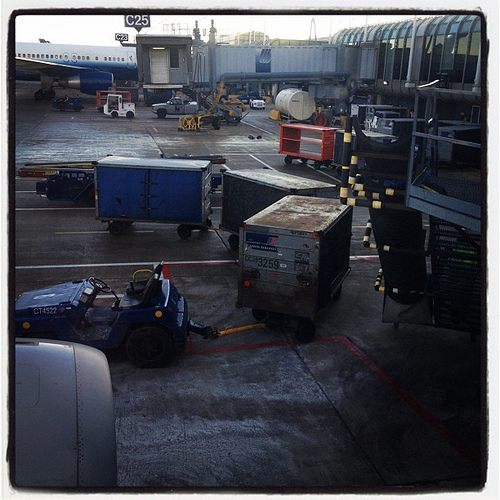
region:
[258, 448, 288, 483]
the ground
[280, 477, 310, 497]
the ground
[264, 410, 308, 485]
the ground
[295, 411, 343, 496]
the ground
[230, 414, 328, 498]
the ground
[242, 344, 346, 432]
the ground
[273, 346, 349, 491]
the ground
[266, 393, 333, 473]
the ground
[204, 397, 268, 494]
the ground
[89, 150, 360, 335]
three carts on tarmac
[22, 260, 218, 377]
blue vehicle on tarmac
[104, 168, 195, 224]
blue side of luggage cart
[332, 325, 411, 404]
red line on tarmac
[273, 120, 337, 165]
empty orange cart on wheels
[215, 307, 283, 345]
yellow rod on cart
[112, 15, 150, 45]
white and blue signs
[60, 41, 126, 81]
body of parked airplane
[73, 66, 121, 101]
blue jet engine under wing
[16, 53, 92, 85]
wing on side of plane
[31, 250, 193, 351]
vehicle on a tarmack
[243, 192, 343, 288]
container on a trarmack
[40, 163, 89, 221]
truck on the tarmack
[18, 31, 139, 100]
airplane at the gate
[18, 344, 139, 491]
engine of an airplane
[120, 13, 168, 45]
sign at an airport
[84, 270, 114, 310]
steering wheel of vehicle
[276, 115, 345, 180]
red cart on the tarmack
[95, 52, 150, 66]
windows on airplane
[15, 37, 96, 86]
wing on an airplane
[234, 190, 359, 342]
luggage cart on the tarmac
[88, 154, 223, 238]
luggage cart on the tarmac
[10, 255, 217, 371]
truck to pull luggage carts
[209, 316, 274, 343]
yellow tow bar on the cart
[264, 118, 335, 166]
an orange luggage cart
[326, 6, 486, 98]
airport terminal with glass windows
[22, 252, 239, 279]
white line on the tarmac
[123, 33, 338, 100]
the jetway on the tarmac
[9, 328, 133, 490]
part of a jet engine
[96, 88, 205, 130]
two vehicles on the tarmac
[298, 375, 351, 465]
There is a grey color of cement at the airport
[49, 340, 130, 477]
There is a bright grey turbine on the wing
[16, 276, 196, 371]
There is a blue baggage-carrying vehicle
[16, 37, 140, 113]
There is a blue and white plane in the distance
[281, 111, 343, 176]
There is a red metal cart on the side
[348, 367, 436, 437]
There is a red line that is on the ground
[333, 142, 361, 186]
There are poles with black and yellow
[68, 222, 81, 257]
There is a yellow line that is on the ground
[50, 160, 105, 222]
There is a vehicle in the distance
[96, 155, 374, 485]
This took place in Dayton, Ohio